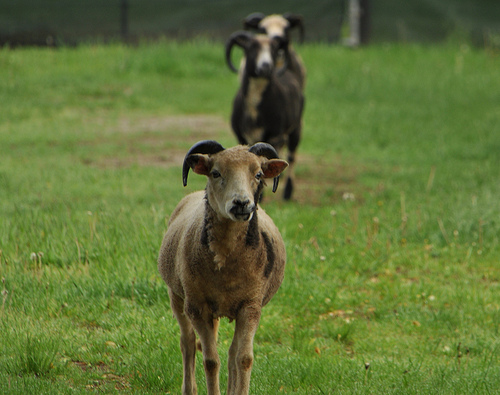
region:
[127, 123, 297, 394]
brown ram with black markings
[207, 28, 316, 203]
black ram with white markings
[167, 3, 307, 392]
three rams walking in a line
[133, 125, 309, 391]
brown ram with black curved horns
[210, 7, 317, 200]
2 black rams with black curved horns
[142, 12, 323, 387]
3 rams walking in a field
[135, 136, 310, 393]
brown sheep walking in a field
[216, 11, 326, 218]
two black sheep standing in a field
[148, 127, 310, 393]
brown ram has white muzzle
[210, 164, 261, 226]
white muzzle on brown ram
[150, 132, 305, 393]
A ram in a grassy field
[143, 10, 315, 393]
a group of 3 goats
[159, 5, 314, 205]
they all have long horns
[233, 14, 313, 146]
these goats are black & white & brown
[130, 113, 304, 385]
this one is brown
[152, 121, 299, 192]
the horns are black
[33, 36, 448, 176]
the grass appears to be fairly long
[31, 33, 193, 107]
the goats should have some good grazing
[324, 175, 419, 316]
some kind of flower is blooming.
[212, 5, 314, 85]
both these goats have big black horns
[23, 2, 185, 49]
it appears to be a wall in the back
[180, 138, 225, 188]
a goats black horn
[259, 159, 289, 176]
the goats brown ears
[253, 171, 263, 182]
the goats dark eyes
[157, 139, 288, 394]
a brown goat on the field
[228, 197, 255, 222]
the dark nose and lips of the goat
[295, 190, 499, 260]
wild flowers growing in the field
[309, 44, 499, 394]
the green field for grazing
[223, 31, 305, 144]
a brown goat with a white face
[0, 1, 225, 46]
a fence in the background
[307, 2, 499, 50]
a privacy screen on the fence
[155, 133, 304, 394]
a brown ram outside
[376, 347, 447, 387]
green grass on the ground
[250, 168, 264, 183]
left eye of the ram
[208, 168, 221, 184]
right eye of the ram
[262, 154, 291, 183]
left ear on ram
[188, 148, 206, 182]
right ear on ram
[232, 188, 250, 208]
nose on the ram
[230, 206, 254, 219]
mouth of the ram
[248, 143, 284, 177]
horn on the ram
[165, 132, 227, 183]
right horn on ram